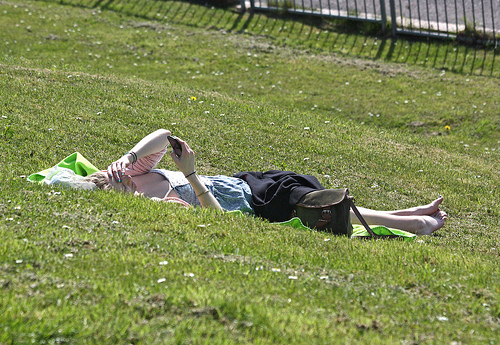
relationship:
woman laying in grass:
[44, 118, 452, 255] [3, 0, 498, 343]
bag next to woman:
[284, 184, 400, 241] [44, 118, 452, 255]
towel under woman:
[26, 147, 418, 244] [44, 118, 452, 255]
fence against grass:
[245, 0, 498, 48] [3, 0, 498, 343]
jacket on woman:
[233, 167, 328, 228] [44, 118, 452, 255]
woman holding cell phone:
[44, 118, 452, 255] [165, 135, 184, 161]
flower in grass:
[303, 124, 312, 138] [3, 0, 498, 343]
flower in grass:
[92, 109, 107, 122] [3, 0, 498, 343]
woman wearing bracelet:
[44, 118, 452, 255] [195, 188, 215, 202]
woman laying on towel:
[44, 118, 452, 255] [26, 147, 418, 244]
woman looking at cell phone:
[44, 118, 452, 255] [165, 135, 184, 161]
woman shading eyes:
[44, 118, 452, 255] [115, 170, 129, 193]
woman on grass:
[44, 118, 452, 255] [3, 0, 498, 343]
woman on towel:
[44, 118, 452, 255] [26, 147, 418, 244]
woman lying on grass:
[44, 118, 452, 255] [3, 0, 498, 343]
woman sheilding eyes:
[44, 118, 452, 255] [115, 170, 129, 193]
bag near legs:
[284, 184, 400, 241] [351, 197, 452, 239]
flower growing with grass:
[303, 124, 312, 138] [3, 0, 498, 343]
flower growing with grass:
[92, 109, 107, 122] [3, 0, 498, 343]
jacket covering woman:
[233, 167, 328, 228] [44, 118, 452, 255]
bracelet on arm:
[195, 188, 215, 202] [167, 136, 221, 210]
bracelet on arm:
[181, 167, 200, 179] [167, 136, 221, 210]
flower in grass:
[185, 94, 201, 107] [3, 0, 498, 343]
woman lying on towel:
[44, 118, 452, 255] [26, 147, 418, 244]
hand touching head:
[106, 153, 130, 184] [91, 160, 140, 199]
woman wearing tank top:
[44, 118, 452, 255] [140, 163, 256, 217]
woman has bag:
[44, 118, 452, 255] [284, 184, 400, 241]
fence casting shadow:
[245, 0, 498, 48] [56, 0, 499, 79]